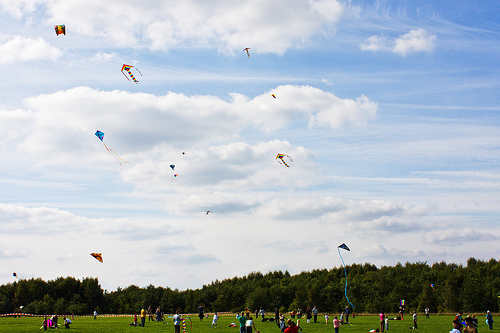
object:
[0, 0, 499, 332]
background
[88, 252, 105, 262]
kite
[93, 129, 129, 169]
kite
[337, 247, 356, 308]
tail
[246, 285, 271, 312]
trees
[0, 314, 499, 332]
field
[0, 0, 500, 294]
sky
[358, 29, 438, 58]
clouds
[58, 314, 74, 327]
people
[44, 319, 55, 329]
kite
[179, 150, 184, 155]
kite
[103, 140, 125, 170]
tail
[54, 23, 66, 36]
kite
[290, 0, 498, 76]
air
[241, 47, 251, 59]
kite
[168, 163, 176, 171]
kite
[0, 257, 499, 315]
forrest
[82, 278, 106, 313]
trees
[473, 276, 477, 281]
leaves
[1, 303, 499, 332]
crowd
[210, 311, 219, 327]
people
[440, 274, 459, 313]
trees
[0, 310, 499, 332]
park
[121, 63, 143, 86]
kite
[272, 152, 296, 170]
kite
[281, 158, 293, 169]
tail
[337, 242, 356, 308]
kite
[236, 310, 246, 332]
person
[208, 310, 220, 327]
person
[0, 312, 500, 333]
grass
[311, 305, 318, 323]
people